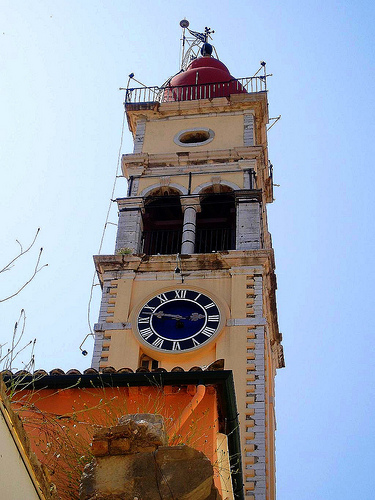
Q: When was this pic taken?
A: During the daytime.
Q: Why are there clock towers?
A: So people know the time.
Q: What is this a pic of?
A: A clock tower.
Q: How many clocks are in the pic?
A: 1.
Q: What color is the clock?
A: Black.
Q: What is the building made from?
A: Brick.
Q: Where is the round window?
A: Above the clock.